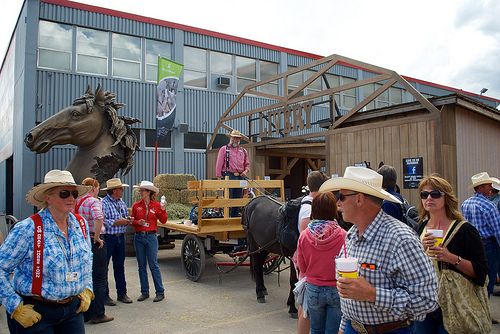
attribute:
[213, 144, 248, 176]
shirt — red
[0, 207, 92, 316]
shirt — blue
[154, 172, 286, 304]
horsecart — wooden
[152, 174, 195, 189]
hay — block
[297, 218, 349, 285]
hoodie — pink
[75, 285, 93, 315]
glove — yellow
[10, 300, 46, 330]
glove — yellow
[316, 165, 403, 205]
hat — white, cowboy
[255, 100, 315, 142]
livery — wood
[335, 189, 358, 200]
sunglasses — black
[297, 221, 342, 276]
hoodie — pink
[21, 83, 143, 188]
horse's head — statue, brown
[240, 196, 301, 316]
horse — black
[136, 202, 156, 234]
suspenders — red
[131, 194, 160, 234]
shirt — red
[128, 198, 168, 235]
shirt — red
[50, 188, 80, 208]
sunglasses — dark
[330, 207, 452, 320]
shirt — plaid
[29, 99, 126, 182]
horse — statue